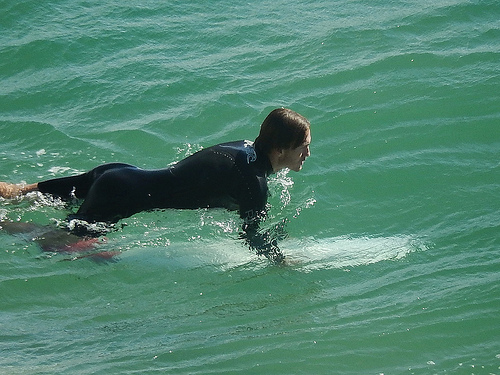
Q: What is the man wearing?
A: A wetsuit.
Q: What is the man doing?
A: Surfing.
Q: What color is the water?
A: Green.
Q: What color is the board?
A: White.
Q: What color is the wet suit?
A: Black.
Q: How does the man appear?
A: Wet.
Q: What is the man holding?
A: A surfboard.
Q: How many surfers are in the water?
A: 1.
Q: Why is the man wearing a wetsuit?
A: To surf.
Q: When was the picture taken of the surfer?
A: Summer evening.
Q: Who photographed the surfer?
A: Man on a boat.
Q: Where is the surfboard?
A: Underneath the water.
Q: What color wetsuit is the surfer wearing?
A: Black.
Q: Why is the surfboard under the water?
A: Body weight.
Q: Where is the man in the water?
A: Ocean.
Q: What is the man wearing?
A: Wet suit.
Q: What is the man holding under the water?
A: Surfboard.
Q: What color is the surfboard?
A: White.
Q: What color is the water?
A: Green.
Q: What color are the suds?
A: White.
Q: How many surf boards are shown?
A: One.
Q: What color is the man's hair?
A: Brown.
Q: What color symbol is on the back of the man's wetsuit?
A: Blue.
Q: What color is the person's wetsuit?
A: Black.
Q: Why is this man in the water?
A: Surfing.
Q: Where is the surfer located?
A: Ocean.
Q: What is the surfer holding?
A: Surfboard.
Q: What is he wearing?
A: Wetsuit.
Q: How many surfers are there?
A: 1.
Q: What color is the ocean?
A: Greenish blue.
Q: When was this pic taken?
A: During the day.